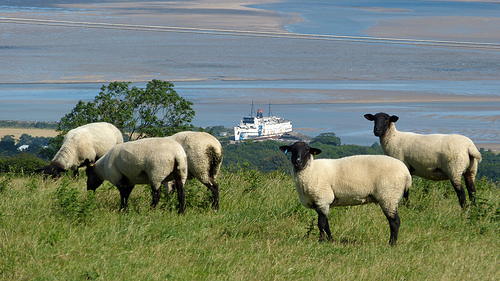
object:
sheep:
[278, 141, 414, 247]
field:
[5, 119, 498, 278]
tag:
[284, 149, 287, 154]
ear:
[279, 145, 291, 153]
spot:
[87, 160, 95, 166]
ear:
[84, 158, 91, 167]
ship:
[233, 98, 294, 142]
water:
[0, 4, 499, 146]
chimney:
[257, 108, 263, 119]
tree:
[39, 78, 196, 161]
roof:
[17, 144, 49, 150]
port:
[194, 114, 304, 146]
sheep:
[85, 137, 189, 216]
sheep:
[363, 112, 483, 212]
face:
[373, 113, 389, 134]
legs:
[317, 207, 329, 243]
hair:
[470, 147, 483, 163]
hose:
[293, 154, 300, 159]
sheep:
[31, 122, 124, 186]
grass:
[0, 173, 500, 280]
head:
[279, 141, 323, 169]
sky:
[317, 12, 346, 37]